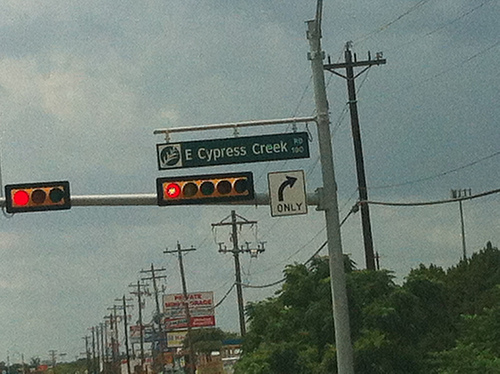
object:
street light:
[154, 170, 255, 208]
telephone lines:
[364, 9, 453, 222]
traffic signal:
[0, 179, 73, 215]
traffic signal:
[153, 170, 254, 207]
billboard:
[161, 287, 217, 330]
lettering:
[162, 292, 211, 303]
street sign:
[155, 129, 311, 173]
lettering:
[181, 139, 293, 163]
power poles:
[204, 210, 270, 337]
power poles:
[163, 232, 206, 372]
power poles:
[133, 257, 173, 347]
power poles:
[127, 276, 153, 373]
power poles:
[83, 262, 167, 359]